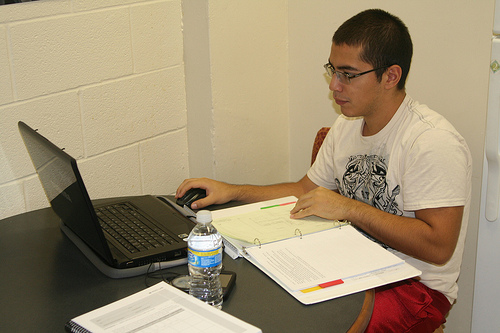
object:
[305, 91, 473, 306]
t-shirt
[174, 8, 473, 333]
man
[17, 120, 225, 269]
laptop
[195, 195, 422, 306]
booklet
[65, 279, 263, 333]
booklet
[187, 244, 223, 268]
label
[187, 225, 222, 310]
water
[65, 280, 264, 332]
book stack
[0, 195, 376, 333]
table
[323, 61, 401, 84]
eyeglasses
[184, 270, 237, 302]
cell phone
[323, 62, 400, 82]
frame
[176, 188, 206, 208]
mouse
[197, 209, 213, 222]
bottle cap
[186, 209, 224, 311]
bottle